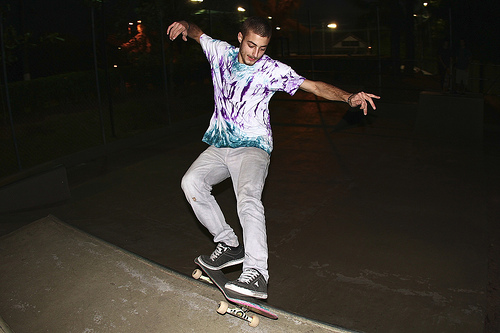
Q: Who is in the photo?
A: A man.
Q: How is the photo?
A: Clear.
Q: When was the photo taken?
A: Nighttime.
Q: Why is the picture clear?
A: Its outside.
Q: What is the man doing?
A: Skating.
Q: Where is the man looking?
A: His shoes.